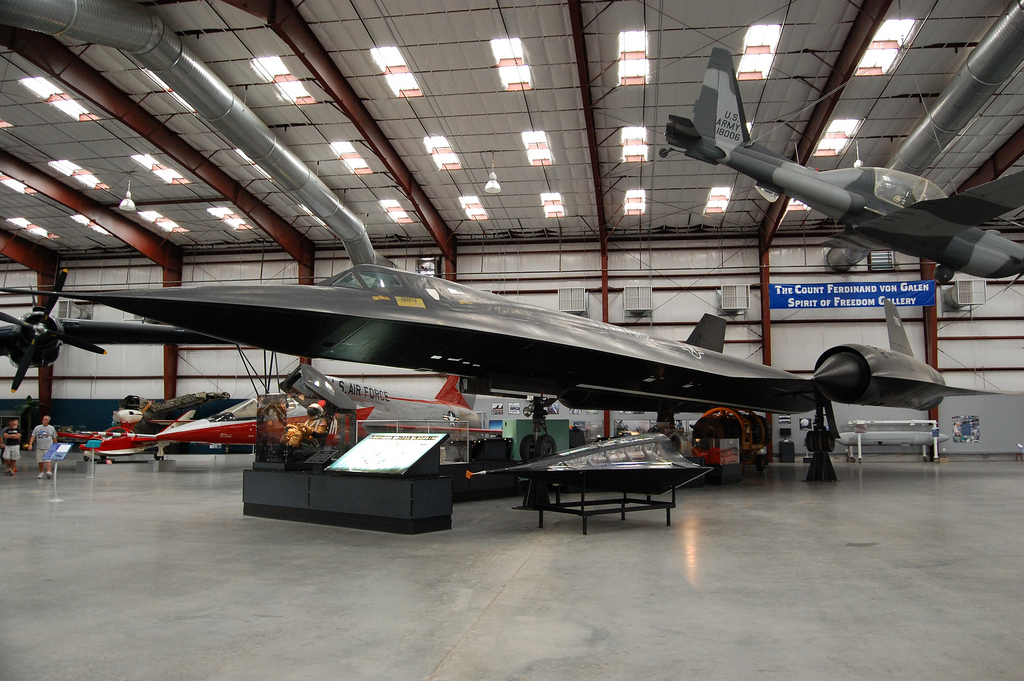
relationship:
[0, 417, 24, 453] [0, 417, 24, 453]
man with a shirt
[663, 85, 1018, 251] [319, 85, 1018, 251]
plane hanging from ceiling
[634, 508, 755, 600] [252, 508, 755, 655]
glare on floor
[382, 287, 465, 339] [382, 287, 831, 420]
sticker on a plane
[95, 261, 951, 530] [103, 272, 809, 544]
aircraft in hangar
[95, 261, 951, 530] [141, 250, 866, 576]
aircraft in hangar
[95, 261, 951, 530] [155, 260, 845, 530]
aircraft in hangar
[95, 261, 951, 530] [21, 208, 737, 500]
aircraft in hangar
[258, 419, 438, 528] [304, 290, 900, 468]
plaque in front of plane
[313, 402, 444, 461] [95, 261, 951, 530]
plaque in front of aircraft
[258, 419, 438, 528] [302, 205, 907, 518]
plaque in front of plane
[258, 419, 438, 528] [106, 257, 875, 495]
plaque in front of airplane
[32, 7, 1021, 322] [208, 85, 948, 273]
building has a light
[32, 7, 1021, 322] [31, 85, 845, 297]
building has a light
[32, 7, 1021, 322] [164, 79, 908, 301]
building has a light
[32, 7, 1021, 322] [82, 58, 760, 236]
building has a light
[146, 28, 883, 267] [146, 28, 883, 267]
building has a light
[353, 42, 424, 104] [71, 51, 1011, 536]
light in a warehouse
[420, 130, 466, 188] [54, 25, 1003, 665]
light in warehouse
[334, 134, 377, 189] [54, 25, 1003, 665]
light in warehouse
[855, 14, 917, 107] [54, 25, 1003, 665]
light in warehouse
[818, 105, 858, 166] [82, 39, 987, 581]
light in warehouse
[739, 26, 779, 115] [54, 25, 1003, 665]
light in warehouse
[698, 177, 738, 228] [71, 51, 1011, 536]
light in warehouse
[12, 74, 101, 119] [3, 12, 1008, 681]
light in hangar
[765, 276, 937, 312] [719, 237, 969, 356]
sign on wall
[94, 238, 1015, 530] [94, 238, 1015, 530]
aircraft in hangar